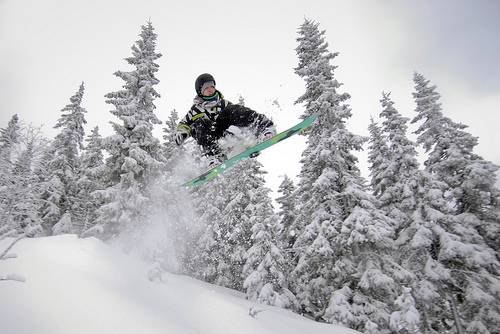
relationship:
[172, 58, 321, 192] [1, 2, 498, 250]
snowboarder in air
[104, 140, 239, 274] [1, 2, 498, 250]
snow in air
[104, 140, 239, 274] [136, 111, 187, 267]
snow on trees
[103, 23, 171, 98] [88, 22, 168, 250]
top of tree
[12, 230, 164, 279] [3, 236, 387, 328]
top of snow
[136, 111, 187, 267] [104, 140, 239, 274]
trees has snow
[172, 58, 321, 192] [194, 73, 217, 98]
snowboarder has head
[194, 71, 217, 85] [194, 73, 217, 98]
bonnet on head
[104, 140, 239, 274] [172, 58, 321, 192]
snow caused by snowboarder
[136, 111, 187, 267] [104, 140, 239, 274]
trees covered with snow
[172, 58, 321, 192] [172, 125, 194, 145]
snowboarder has right hand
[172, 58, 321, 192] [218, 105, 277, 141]
snowboarder has left leg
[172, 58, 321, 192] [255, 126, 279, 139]
snowboarder has left boot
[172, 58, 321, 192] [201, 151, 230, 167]
snowboarder has right boot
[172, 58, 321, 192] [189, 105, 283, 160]
snowboarder has pants